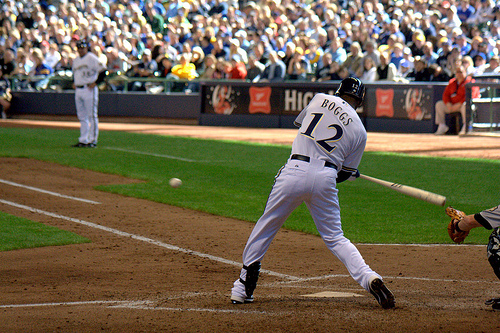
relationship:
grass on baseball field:
[20, 120, 498, 216] [0, 155, 499, 328]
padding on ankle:
[238, 261, 261, 303] [234, 262, 256, 297]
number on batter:
[303, 110, 349, 153] [226, 68, 400, 315]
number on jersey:
[303, 110, 349, 153] [298, 95, 368, 169]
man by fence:
[429, 66, 480, 136] [1, 75, 496, 133]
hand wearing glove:
[443, 205, 472, 243] [442, 201, 474, 245]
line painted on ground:
[0, 199, 301, 281] [0, 152, 497, 329]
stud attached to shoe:
[390, 298, 392, 301] [356, 262, 421, 322]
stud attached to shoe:
[391, 302, 394, 305] [356, 262, 421, 322]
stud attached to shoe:
[380, 298, 383, 300] [356, 262, 421, 322]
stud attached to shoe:
[380, 280, 382, 283] [356, 262, 421, 322]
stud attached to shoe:
[373, 285, 376, 288] [356, 262, 421, 322]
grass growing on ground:
[228, 145, 245, 164] [0, 111, 484, 331]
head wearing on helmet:
[337, 77, 364, 111] [332, 76, 367, 103]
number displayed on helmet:
[352, 84, 357, 88] [332, 76, 367, 103]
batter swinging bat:
[227, 76, 398, 311] [347, 167, 447, 209]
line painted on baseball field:
[1, 295, 131, 308] [1, 111, 484, 328]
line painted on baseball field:
[1, 195, 301, 279] [1, 111, 484, 328]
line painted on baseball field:
[0, 179, 106, 206] [1, 111, 484, 328]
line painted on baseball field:
[0, 199, 301, 281] [1, 111, 484, 328]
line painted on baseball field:
[353, 239, 484, 247] [1, 111, 484, 328]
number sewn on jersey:
[301, 102, 348, 155] [285, 88, 371, 175]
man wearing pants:
[67, 37, 107, 153] [75, 85, 103, 147]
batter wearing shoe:
[227, 76, 398, 311] [367, 272, 397, 308]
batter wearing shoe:
[227, 76, 398, 311] [227, 289, 254, 307]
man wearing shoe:
[67, 37, 107, 153] [70, 139, 89, 148]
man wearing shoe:
[429, 66, 480, 136] [431, 126, 448, 132]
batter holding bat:
[229, 45, 397, 321] [353, 166, 450, 213]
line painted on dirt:
[1, 295, 131, 308] [1, 152, 484, 329]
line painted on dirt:
[0, 199, 301, 281] [1, 152, 484, 329]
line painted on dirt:
[1, 195, 301, 279] [1, 152, 484, 329]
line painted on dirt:
[0, 179, 106, 206] [1, 152, 484, 329]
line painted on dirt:
[262, 272, 338, 289] [1, 152, 484, 329]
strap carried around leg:
[239, 262, 247, 273] [238, 205, 276, 274]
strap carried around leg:
[236, 275, 247, 286] [238, 205, 276, 274]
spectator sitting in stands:
[167, 54, 198, 80] [2, 2, 484, 93]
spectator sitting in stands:
[226, 50, 246, 77] [2, 2, 484, 93]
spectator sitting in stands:
[260, 45, 287, 79] [2, 2, 484, 93]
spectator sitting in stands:
[128, 47, 159, 78] [2, 2, 484, 93]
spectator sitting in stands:
[370, 50, 396, 82] [2, 2, 484, 93]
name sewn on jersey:
[322, 96, 354, 131] [291, 92, 367, 177]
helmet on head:
[336, 76, 367, 103] [333, 76, 364, 104]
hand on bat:
[342, 162, 365, 182] [348, 162, 457, 207]